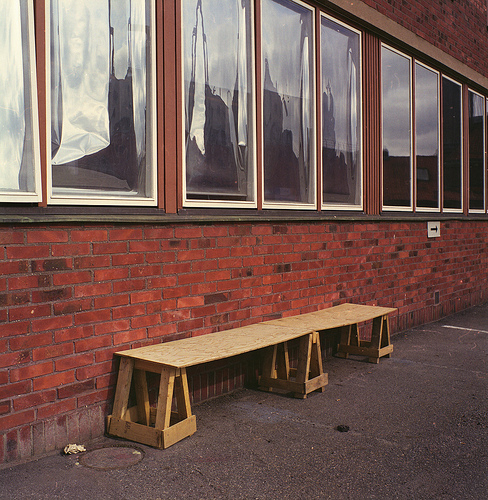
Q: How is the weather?
A: It is cloudy.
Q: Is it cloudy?
A: Yes, it is cloudy.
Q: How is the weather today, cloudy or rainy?
A: It is cloudy.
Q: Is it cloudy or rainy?
A: It is cloudy.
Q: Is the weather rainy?
A: No, it is cloudy.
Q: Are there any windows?
A: Yes, there is a window.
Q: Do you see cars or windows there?
A: Yes, there is a window.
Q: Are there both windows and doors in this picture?
A: No, there is a window but no doors.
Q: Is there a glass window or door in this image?
A: Yes, there is a glass window.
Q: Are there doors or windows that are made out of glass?
A: Yes, the window is made of glass.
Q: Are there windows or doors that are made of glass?
A: Yes, the window is made of glass.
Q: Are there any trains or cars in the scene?
A: No, there are no cars or trains.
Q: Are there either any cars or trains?
A: No, there are no cars or trains.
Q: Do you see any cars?
A: No, there are no cars.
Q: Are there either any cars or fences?
A: No, there are no cars or fences.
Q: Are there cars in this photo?
A: No, there are no cars.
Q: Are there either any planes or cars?
A: No, there are no cars or planes.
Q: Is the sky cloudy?
A: Yes, the sky is cloudy.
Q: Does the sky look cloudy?
A: Yes, the sky is cloudy.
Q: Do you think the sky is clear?
A: No, the sky is cloudy.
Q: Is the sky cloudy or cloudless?
A: The sky is cloudy.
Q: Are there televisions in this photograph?
A: No, there are no televisions.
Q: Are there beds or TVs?
A: No, there are no TVs or beds.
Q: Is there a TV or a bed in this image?
A: No, there are no televisions or beds.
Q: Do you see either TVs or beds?
A: No, there are no TVs or beds.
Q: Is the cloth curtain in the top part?
A: Yes, the curtain is in the top of the image.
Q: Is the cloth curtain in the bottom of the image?
A: No, the curtain is in the top of the image.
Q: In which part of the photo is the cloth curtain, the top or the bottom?
A: The curtain is in the top of the image.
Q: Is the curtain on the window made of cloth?
A: Yes, the curtain is made of cloth.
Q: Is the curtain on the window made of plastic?
A: No, the curtain is made of cloth.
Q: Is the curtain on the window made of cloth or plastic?
A: The curtain is made of cloth.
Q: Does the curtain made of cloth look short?
A: Yes, the curtain is short.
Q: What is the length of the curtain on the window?
A: The curtain is short.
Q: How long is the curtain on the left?
A: The curtain is short.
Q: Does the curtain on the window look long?
A: No, the curtain is short.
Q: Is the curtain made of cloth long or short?
A: The curtain is short.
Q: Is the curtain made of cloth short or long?
A: The curtain is short.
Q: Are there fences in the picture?
A: No, there are no fences.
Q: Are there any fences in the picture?
A: No, there are no fences.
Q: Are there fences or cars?
A: No, there are no fences or cars.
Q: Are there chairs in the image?
A: No, there are no chairs.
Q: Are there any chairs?
A: No, there are no chairs.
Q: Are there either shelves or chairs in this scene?
A: No, there are no chairs or shelves.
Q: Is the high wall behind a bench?
A: Yes, the wall is behind a bench.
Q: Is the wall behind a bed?
A: No, the wall is behind a bench.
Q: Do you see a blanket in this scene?
A: No, there are no blankets.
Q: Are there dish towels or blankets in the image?
A: No, there are no blankets or dish towels.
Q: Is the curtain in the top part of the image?
A: Yes, the curtain is in the top of the image.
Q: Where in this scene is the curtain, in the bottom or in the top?
A: The curtain is in the top of the image.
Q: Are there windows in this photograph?
A: Yes, there is a window.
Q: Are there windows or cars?
A: Yes, there is a window.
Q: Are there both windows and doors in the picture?
A: No, there is a window but no doors.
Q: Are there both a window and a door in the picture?
A: No, there is a window but no doors.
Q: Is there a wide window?
A: Yes, there is a wide window.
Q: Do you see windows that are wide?
A: Yes, there is a window that is wide.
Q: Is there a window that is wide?
A: Yes, there is a window that is wide.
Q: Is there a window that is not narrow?
A: Yes, there is a wide window.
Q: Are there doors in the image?
A: No, there are no doors.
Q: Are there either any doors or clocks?
A: No, there are no doors or clocks.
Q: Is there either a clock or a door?
A: No, there are no doors or clocks.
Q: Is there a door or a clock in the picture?
A: No, there are no doors or clocks.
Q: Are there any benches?
A: Yes, there is a bench.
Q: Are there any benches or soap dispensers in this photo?
A: Yes, there is a bench.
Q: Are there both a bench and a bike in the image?
A: No, there is a bench but no bikes.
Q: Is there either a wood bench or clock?
A: Yes, there is a wood bench.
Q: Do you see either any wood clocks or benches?
A: Yes, there is a wood bench.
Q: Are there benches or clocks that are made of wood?
A: Yes, the bench is made of wood.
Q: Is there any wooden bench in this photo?
A: Yes, there is a wood bench.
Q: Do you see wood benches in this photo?
A: Yes, there is a wood bench.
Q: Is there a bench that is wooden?
A: Yes, there is a bench that is wooden.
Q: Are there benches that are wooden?
A: Yes, there is a bench that is wooden.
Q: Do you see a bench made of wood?
A: Yes, there is a bench that is made of wood.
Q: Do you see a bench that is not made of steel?
A: Yes, there is a bench that is made of wood.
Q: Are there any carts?
A: No, there are no carts.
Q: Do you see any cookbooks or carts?
A: No, there are no carts or cookbooks.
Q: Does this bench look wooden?
A: Yes, the bench is wooden.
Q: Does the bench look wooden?
A: Yes, the bench is wooden.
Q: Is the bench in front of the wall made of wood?
A: Yes, the bench is made of wood.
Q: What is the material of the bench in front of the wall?
A: The bench is made of wood.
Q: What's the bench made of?
A: The bench is made of wood.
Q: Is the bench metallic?
A: No, the bench is wooden.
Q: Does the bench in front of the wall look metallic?
A: No, the bench is wooden.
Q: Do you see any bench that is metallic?
A: No, there is a bench but it is wooden.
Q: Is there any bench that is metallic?
A: No, there is a bench but it is wooden.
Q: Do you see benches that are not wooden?
A: No, there is a bench but it is wooden.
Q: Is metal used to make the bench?
A: No, the bench is made of wood.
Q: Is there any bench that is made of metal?
A: No, there is a bench but it is made of wood.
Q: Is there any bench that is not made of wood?
A: No, there is a bench but it is made of wood.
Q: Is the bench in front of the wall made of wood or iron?
A: The bench is made of wood.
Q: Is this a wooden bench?
A: Yes, this is a wooden bench.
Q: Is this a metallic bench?
A: No, this is a wooden bench.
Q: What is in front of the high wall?
A: The bench is in front of the wall.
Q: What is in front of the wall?
A: The bench is in front of the wall.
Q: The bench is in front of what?
A: The bench is in front of the wall.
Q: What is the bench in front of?
A: The bench is in front of the wall.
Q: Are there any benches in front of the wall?
A: Yes, there is a bench in front of the wall.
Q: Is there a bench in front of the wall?
A: Yes, there is a bench in front of the wall.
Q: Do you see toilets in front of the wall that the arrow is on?
A: No, there is a bench in front of the wall.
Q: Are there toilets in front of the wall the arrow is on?
A: No, there is a bench in front of the wall.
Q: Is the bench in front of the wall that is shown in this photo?
A: Yes, the bench is in front of the wall.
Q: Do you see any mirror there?
A: No, there are no mirrors.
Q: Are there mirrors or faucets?
A: No, there are no mirrors or faucets.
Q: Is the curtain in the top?
A: Yes, the curtain is in the top of the image.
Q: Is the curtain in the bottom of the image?
A: No, the curtain is in the top of the image.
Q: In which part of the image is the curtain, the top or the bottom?
A: The curtain is in the top of the image.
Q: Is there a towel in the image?
A: No, there are no towels.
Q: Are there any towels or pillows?
A: No, there are no towels or pillows.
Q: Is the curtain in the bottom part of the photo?
A: No, the curtain is in the top of the image.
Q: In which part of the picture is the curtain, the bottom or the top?
A: The curtain is in the top of the image.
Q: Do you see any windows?
A: Yes, there is a window.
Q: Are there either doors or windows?
A: Yes, there is a window.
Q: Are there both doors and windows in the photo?
A: No, there is a window but no doors.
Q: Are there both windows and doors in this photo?
A: No, there is a window but no doors.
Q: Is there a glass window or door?
A: Yes, there is a glass window.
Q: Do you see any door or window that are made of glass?
A: Yes, the window is made of glass.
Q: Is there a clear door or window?
A: Yes, there is a clear window.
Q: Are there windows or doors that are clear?
A: Yes, the window is clear.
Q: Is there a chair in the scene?
A: No, there are no chairs.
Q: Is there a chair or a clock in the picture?
A: No, there are no chairs or clocks.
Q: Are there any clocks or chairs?
A: No, there are no chairs or clocks.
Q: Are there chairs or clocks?
A: No, there are no chairs or clocks.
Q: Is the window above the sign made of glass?
A: Yes, the window is made of glass.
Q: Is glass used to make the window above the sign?
A: Yes, the window is made of glass.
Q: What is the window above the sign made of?
A: The window is made of glass.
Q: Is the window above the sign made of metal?
A: No, the window is made of glass.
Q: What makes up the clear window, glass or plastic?
A: The window is made of glass.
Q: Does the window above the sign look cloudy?
A: No, the window is clear.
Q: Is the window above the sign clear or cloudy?
A: The window is clear.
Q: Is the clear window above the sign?
A: Yes, the window is above the sign.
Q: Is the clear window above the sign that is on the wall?
A: Yes, the window is above the sign.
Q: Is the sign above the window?
A: No, the window is above the sign.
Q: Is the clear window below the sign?
A: No, the window is above the sign.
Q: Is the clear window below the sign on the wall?
A: No, the window is above the sign.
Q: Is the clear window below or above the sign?
A: The window is above the sign.